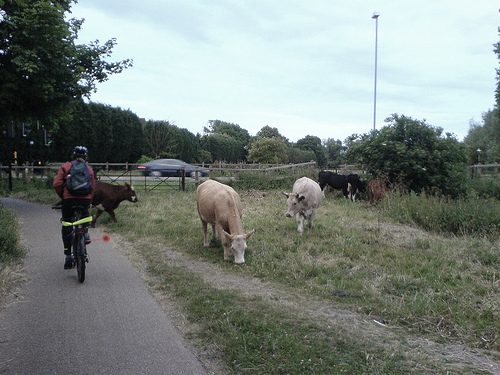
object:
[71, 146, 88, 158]
helmet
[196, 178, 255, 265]
cow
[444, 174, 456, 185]
foliage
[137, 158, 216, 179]
car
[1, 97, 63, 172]
house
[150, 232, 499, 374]
path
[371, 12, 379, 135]
pole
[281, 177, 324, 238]
cow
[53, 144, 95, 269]
person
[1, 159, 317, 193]
fence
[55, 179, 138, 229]
cow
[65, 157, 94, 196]
backpack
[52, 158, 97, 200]
jacket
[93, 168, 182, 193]
gate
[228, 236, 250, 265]
white face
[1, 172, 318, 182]
road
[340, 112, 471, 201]
tree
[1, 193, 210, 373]
path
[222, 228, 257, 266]
white head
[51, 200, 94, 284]
bike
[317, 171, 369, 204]
cow